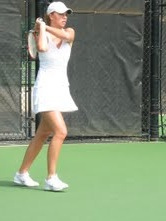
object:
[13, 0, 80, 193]
girl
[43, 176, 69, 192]
shoes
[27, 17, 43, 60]
racquet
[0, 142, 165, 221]
court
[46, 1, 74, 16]
cap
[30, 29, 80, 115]
dress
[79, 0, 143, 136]
backdrop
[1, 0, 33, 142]
gate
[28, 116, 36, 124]
hinge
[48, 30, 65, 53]
v-neck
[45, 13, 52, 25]
hair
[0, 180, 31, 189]
shadow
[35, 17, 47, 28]
hand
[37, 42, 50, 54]
elbow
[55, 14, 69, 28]
face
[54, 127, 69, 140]
knee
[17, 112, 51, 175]
leg